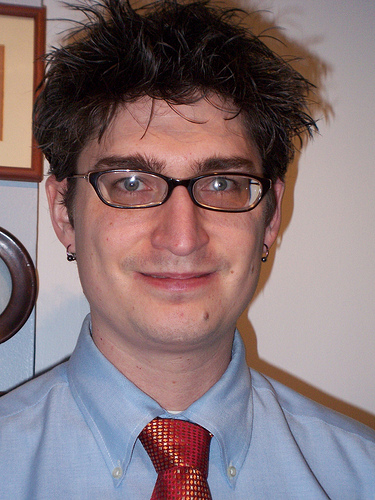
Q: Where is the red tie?
A: Around the man's neck.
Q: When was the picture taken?
A: At night.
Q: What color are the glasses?
A: Black.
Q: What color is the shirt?
A: Blue.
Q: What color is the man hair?
A: Brown.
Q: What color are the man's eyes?
A: Green.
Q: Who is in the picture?
A: A man.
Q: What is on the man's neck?
A: A tie.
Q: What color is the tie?
A: Red.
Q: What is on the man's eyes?
A: Glasses.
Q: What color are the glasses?
A: Black.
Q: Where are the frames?
A: On the wall.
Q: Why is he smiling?
A: Posing.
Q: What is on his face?
A: Glasses.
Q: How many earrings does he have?
A: 2.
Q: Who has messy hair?
A: The man.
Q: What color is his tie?
A: Red.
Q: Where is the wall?
A: Behind the man.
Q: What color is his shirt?
A: Blue.